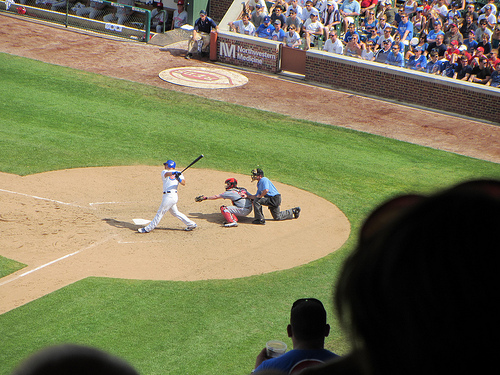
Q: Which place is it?
A: It is a field.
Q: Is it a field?
A: Yes, it is a field.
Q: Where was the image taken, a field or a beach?
A: It was taken at a field.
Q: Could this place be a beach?
A: No, it is a field.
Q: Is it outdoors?
A: Yes, it is outdoors.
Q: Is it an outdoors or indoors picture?
A: It is outdoors.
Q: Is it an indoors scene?
A: No, it is outdoors.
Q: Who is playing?
A: The people are playing.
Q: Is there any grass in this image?
A: Yes, there is grass.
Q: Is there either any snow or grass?
A: Yes, there is grass.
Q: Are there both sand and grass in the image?
A: No, there is grass but no sand.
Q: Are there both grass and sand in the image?
A: No, there is grass but no sand.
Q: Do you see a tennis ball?
A: No, there are no tennis balls.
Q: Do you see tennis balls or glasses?
A: No, there are no tennis balls or glasses.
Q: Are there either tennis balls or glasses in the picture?
A: No, there are no tennis balls or glasses.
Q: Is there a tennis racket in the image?
A: No, there are no rackets.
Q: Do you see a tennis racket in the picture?
A: No, there are no rackets.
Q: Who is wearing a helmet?
A: The player is wearing a helmet.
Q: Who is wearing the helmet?
A: The player is wearing a helmet.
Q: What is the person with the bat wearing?
A: The player is wearing a helmet.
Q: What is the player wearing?
A: The player is wearing a helmet.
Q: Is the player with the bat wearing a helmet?
A: Yes, the player is wearing a helmet.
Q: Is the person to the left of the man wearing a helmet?
A: Yes, the player is wearing a helmet.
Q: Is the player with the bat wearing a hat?
A: No, the player is wearing a helmet.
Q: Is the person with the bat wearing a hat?
A: No, the player is wearing a helmet.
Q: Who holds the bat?
A: The player holds the bat.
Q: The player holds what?
A: The player holds the bat.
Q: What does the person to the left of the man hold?
A: The player holds the bat.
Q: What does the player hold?
A: The player holds the bat.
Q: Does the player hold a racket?
A: No, the player holds the bat.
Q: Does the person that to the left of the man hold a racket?
A: No, the player holds the bat.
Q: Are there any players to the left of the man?
A: Yes, there is a player to the left of the man.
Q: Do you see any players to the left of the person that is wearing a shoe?
A: Yes, there is a player to the left of the man.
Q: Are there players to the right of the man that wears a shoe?
A: No, the player is to the left of the man.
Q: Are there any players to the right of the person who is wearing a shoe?
A: No, the player is to the left of the man.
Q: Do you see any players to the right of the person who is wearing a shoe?
A: No, the player is to the left of the man.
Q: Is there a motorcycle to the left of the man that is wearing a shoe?
A: No, there is a player to the left of the man.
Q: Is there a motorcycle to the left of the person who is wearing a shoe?
A: No, there is a player to the left of the man.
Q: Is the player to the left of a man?
A: Yes, the player is to the left of a man.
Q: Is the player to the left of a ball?
A: No, the player is to the left of a man.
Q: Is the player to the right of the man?
A: No, the player is to the left of the man.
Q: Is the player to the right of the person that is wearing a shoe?
A: No, the player is to the left of the man.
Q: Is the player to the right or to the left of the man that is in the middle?
A: The player is to the left of the man.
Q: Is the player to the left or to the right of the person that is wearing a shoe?
A: The player is to the left of the man.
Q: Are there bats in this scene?
A: Yes, there is a bat.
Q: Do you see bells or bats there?
A: Yes, there is a bat.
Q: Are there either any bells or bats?
A: Yes, there is a bat.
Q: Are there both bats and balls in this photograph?
A: No, there is a bat but no balls.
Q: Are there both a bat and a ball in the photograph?
A: No, there is a bat but no balls.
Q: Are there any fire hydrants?
A: No, there are no fire hydrants.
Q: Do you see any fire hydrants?
A: No, there are no fire hydrants.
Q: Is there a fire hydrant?
A: No, there are no fire hydrants.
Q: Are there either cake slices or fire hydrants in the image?
A: No, there are no fire hydrants or cake slices.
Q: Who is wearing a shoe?
A: The man is wearing a shoe.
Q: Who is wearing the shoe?
A: The man is wearing a shoe.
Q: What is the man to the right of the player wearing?
A: The man is wearing a shoe.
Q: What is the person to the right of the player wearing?
A: The man is wearing a shoe.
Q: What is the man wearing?
A: The man is wearing a shoe.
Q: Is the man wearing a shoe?
A: Yes, the man is wearing a shoe.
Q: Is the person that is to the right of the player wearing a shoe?
A: Yes, the man is wearing a shoe.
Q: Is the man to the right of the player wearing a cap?
A: No, the man is wearing a shoe.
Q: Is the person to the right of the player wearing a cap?
A: No, the man is wearing a shoe.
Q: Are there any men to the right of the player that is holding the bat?
A: Yes, there is a man to the right of the player.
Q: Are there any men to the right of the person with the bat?
A: Yes, there is a man to the right of the player.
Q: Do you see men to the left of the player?
A: No, the man is to the right of the player.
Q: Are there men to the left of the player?
A: No, the man is to the right of the player.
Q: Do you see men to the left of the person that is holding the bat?
A: No, the man is to the right of the player.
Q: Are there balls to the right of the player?
A: No, there is a man to the right of the player.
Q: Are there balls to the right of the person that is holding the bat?
A: No, there is a man to the right of the player.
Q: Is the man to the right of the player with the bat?
A: Yes, the man is to the right of the player.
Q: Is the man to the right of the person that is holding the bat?
A: Yes, the man is to the right of the player.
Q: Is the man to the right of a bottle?
A: No, the man is to the right of the player.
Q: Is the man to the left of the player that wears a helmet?
A: No, the man is to the right of the player.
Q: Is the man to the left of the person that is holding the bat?
A: No, the man is to the right of the player.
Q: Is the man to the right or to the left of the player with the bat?
A: The man is to the right of the player.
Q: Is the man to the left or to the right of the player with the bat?
A: The man is to the right of the player.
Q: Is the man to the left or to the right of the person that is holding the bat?
A: The man is to the right of the player.